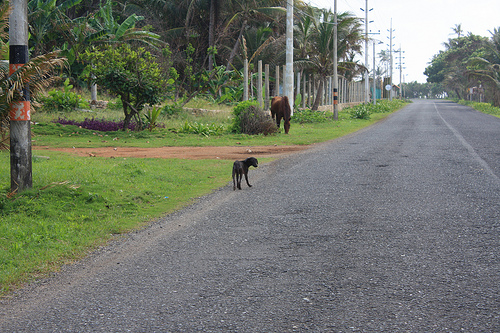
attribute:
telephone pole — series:
[364, 0, 371, 103]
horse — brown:
[267, 89, 296, 136]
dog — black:
[230, 156, 260, 191]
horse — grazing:
[256, 100, 338, 162]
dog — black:
[228, 153, 268, 204]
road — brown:
[105, 133, 218, 168]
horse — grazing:
[269, 93, 294, 136]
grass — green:
[0, 140, 230, 285]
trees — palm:
[49, 4, 171, 69]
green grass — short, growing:
[0, 159, 228, 271]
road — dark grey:
[362, 66, 498, 319]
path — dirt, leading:
[33, 122, 315, 172]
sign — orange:
[6, 54, 33, 129]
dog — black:
[232, 156, 258, 186]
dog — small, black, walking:
[233, 153, 259, 189]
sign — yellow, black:
[330, 84, 340, 104]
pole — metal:
[328, 0, 343, 119]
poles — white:
[279, 0, 340, 120]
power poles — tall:
[3, 2, 408, 197]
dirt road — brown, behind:
[31, 126, 307, 168]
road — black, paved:
[2, 61, 498, 330]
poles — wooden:
[240, 62, 375, 122]